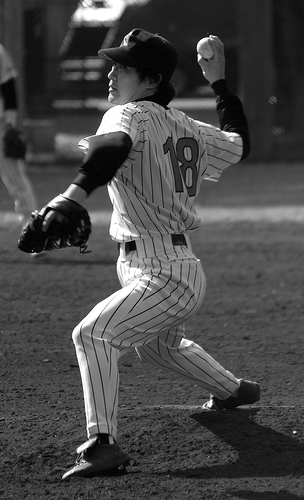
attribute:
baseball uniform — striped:
[48, 185, 269, 452]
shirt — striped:
[99, 187, 204, 273]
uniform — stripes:
[48, 109, 233, 425]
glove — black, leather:
[8, 190, 97, 247]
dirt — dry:
[3, 167, 303, 499]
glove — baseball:
[16, 191, 92, 253]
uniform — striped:
[71, 100, 242, 439]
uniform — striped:
[64, 89, 245, 379]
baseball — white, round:
[193, 35, 221, 61]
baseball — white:
[193, 35, 224, 63]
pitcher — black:
[62, 30, 263, 478]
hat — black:
[98, 23, 177, 74]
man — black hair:
[17, 24, 260, 480]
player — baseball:
[31, 25, 267, 444]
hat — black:
[96, 26, 177, 70]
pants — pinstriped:
[59, 232, 261, 478]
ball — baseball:
[174, 36, 224, 63]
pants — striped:
[45, 244, 240, 477]